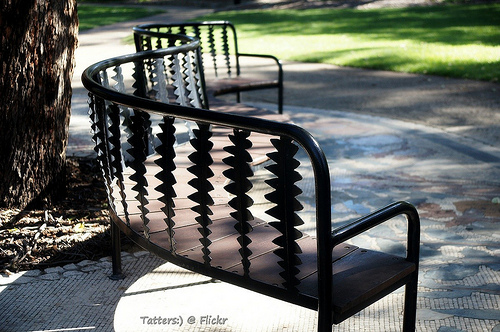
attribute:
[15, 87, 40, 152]
tree — large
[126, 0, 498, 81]
grass — green